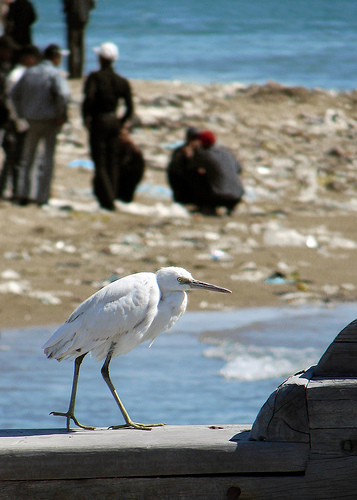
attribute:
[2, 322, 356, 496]
fence — wooden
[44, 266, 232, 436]
bird — white, standing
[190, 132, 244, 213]
person — standing, squatting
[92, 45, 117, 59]
cap — white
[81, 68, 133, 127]
shirt — black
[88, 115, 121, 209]
pants — black, grey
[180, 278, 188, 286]
eye — yellow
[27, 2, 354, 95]
water — blue, wavy, small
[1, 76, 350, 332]
ground — brown